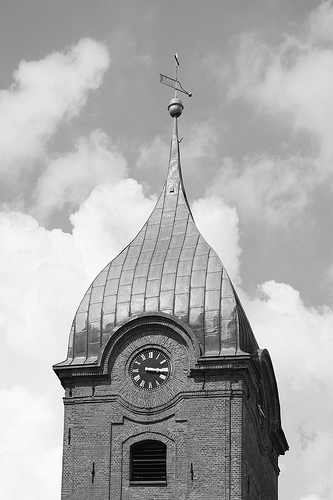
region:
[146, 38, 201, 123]
old weather vane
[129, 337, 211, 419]
clock face with roman numerals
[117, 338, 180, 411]
The time is 3:15.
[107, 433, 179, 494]
a vent for the clock tower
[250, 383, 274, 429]
clock face with white arms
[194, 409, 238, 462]
brick wall clock tower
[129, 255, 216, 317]
shiny tiled roof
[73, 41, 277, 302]
pointed roof on clock tower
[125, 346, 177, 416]
round clock in old tower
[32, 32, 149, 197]
clouds in the sky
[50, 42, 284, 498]
The tower is brick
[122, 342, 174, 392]
the tower has a clock on it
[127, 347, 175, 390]
the numbers on the clock are roman numerals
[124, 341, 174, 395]
the numbers on the clock are white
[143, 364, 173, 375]
the hands on the clock are white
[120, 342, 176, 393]
the time on the clock is 3:15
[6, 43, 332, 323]
the sky is cloudy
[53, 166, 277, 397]
the tower has tiles on the roof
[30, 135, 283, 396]
the tiles are reflecting the light from the sky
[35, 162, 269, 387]
the tiles are shiny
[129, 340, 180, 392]
Clock pointing at three o clock.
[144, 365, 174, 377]
Hour hand pointing at three o clock.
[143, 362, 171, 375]
Minute hand pointing at 3 o clock.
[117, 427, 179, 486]
Black window.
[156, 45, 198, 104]
Weathervane.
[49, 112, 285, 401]
Metal roofing of building.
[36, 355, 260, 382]
Trim of the roof.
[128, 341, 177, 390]
Hour markings of clock.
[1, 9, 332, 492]
Sky with many clouds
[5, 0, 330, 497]
Fluffy white clouds.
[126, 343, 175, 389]
The face of a clock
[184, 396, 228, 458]
Bricks on a building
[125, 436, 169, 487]
A shuttered window on the side of a building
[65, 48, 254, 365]
A building's steeple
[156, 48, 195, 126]
An ornament at the tip of a steeple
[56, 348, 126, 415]
Intricate designs on a building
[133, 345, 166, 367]
Roman numerals on a clock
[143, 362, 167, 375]
The hands on a clock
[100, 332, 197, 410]
A clock on a brick building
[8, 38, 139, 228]
A cloudy sky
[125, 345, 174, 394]
clock on top of tower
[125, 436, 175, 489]
grated window on top of clock tower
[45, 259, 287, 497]
clock tower made of bricks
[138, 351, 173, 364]
roman numerals on a clock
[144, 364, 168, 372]
arms of a clock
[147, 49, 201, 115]
weather vane on top of clock tower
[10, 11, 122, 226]
clouds spread through sky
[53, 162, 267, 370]
metallic roof of clock tower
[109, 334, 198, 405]
circularly lined bricks around clock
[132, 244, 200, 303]
tiled roof of clock tower